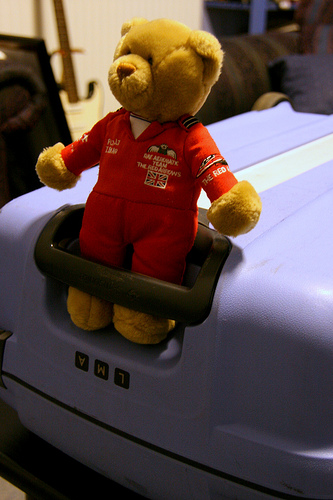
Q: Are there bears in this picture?
A: Yes, there is a bear.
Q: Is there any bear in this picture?
A: Yes, there is a bear.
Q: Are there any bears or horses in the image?
A: Yes, there is a bear.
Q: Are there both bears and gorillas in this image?
A: No, there is a bear but no gorillas.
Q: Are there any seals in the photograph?
A: No, there are no seals.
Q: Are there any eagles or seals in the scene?
A: No, there are no seals or eagles.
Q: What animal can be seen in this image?
A: The animal is a bear.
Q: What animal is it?
A: The animal is a bear.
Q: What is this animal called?
A: That is a bear.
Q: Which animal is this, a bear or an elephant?
A: That is a bear.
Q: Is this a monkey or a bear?
A: This is a bear.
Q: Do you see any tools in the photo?
A: No, there are no tools.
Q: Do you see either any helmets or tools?
A: No, there are no tools or helmets.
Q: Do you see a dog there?
A: No, there are no dogs.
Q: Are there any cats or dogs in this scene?
A: No, there are no dogs or cats.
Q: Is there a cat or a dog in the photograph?
A: No, there are no dogs or cats.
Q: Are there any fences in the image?
A: No, there are no fences.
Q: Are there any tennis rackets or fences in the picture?
A: No, there are no fences or tennis rackets.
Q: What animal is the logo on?
A: The logo is on the bear.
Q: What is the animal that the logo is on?
A: The animal is a bear.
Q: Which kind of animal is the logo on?
A: The logo is on the bear.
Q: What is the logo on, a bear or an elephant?
A: The logo is on a bear.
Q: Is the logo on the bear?
A: Yes, the logo is on the bear.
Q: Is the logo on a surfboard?
A: No, the logo is on the bear.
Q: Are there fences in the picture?
A: No, there are no fences.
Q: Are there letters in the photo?
A: Yes, there are letters.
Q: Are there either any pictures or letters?
A: Yes, there are letters.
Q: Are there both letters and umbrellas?
A: No, there are letters but no umbrellas.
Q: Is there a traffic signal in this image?
A: No, there are no traffic lights.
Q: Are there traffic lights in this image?
A: No, there are no traffic lights.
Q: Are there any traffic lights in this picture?
A: No, there are no traffic lights.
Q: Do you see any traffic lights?
A: No, there are no traffic lights.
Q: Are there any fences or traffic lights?
A: No, there are no traffic lights or fences.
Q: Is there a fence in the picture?
A: No, there are no fences.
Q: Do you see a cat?
A: No, there are no cats.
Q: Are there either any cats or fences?
A: No, there are no cats or fences.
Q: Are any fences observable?
A: No, there are no fences.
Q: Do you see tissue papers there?
A: No, there are no tissue papers.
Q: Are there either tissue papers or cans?
A: No, there are no tissue papers or cans.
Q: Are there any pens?
A: No, there are no pens.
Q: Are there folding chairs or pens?
A: No, there are no pens or folding chairs.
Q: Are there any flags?
A: Yes, there is a flag.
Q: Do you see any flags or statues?
A: Yes, there is a flag.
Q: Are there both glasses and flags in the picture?
A: No, there is a flag but no glasses.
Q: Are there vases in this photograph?
A: No, there are no vases.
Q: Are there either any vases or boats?
A: No, there are no vases or boats.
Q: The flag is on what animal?
A: The flag is on the bear.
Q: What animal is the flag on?
A: The flag is on the bear.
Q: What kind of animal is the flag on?
A: The flag is on the bear.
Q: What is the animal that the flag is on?
A: The animal is a bear.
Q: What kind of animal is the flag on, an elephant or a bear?
A: The flag is on a bear.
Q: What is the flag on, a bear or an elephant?
A: The flag is on a bear.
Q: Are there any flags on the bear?
A: Yes, there is a flag on the bear.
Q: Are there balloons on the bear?
A: No, there is a flag on the bear.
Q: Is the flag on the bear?
A: Yes, the flag is on the bear.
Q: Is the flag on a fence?
A: No, the flag is on the bear.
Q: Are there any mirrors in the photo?
A: No, there are no mirrors.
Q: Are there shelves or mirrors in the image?
A: No, there are no mirrors or shelves.